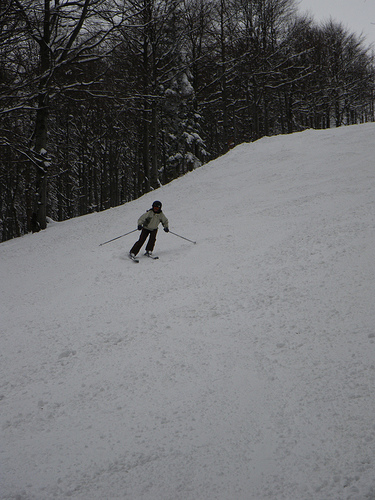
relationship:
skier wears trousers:
[126, 200, 170, 264] [130, 228, 157, 253]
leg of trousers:
[129, 231, 148, 258] [130, 228, 157, 253]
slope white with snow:
[2, 118, 374, 263] [2, 116, 374, 500]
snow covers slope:
[2, 116, 374, 500] [2, 118, 374, 263]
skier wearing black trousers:
[126, 200, 170, 264] [130, 228, 157, 253]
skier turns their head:
[126, 200, 170, 264] [149, 199, 165, 215]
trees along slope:
[3, 2, 369, 244] [2, 118, 374, 263]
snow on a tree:
[2, 116, 374, 500] [151, 51, 209, 178]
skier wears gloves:
[126, 200, 170, 264] [138, 224, 172, 236]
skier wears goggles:
[126, 200, 170, 264] [157, 206, 161, 208]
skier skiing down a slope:
[126, 200, 170, 264] [2, 118, 374, 263]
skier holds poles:
[126, 200, 170, 264] [99, 229, 193, 249]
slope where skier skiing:
[2, 118, 374, 263] [100, 201, 202, 272]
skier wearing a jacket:
[126, 200, 170, 264] [138, 212, 170, 232]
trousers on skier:
[130, 228, 157, 253] [126, 200, 170, 264]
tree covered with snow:
[151, 51, 209, 178] [2, 116, 374, 500]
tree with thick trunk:
[10, 1, 98, 228] [33, 101, 48, 233]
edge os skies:
[128, 252, 137, 262] [128, 251, 160, 264]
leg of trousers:
[145, 229, 157, 256] [130, 228, 157, 253]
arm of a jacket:
[160, 212, 171, 231] [138, 212, 170, 232]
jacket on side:
[138, 212, 170, 232] [139, 210, 151, 228]